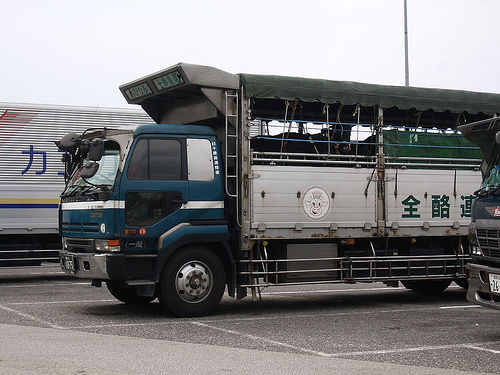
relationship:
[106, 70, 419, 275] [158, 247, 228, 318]
truck has tire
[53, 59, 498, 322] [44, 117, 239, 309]
truck has front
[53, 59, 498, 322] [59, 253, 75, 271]
truck has plate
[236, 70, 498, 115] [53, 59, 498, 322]
roof on truck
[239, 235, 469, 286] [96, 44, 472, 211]
steps on side of truck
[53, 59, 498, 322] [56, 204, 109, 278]
truck has grill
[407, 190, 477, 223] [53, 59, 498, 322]
green writing painted on truck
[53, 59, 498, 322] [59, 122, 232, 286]
truck has cab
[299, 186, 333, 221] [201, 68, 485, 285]
logo painted on trailer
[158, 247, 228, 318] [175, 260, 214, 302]
tire on silver wheel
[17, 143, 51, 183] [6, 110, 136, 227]
writing on silver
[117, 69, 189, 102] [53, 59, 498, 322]
signs on truck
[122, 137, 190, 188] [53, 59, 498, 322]
window on truck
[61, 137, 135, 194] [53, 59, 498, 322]
window on truck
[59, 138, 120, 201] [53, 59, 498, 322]
windshield on truck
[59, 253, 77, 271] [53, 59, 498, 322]
plate on truck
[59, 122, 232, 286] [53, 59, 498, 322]
cab of truck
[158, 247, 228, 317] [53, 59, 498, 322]
tire on truck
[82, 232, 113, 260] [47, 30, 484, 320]
light on truck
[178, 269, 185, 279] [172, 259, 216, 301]
opening on wheel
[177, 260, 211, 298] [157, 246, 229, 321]
opening on wheel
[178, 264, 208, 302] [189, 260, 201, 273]
opening on wheel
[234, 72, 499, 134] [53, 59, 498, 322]
tarp on truck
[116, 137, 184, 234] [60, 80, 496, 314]
door on truck